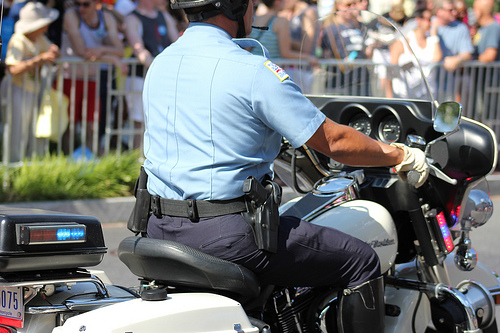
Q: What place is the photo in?
A: It is at the street.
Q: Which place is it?
A: It is a street.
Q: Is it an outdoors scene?
A: Yes, it is outdoors.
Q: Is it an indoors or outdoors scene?
A: It is outdoors.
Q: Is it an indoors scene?
A: No, it is outdoors.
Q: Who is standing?
A: The people are standing.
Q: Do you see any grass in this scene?
A: Yes, there is grass.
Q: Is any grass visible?
A: Yes, there is grass.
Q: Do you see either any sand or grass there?
A: Yes, there is grass.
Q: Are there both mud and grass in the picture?
A: No, there is grass but no mud.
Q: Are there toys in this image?
A: No, there are no toys.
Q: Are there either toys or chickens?
A: No, there are no toys or chickens.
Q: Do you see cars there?
A: No, there are no cars.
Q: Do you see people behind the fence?
A: Yes, there is a person behind the fence.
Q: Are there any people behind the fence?
A: Yes, there is a person behind the fence.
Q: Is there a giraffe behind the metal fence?
A: No, there is a person behind the fence.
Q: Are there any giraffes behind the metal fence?
A: No, there is a person behind the fence.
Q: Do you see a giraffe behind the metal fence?
A: No, there is a person behind the fence.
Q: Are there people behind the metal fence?
A: Yes, there is a person behind the fence.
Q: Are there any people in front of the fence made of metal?
A: No, the person is behind the fence.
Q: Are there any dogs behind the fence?
A: No, there is a person behind the fence.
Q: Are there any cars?
A: No, there are no cars.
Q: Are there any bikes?
A: Yes, there is a bike.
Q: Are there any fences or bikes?
A: Yes, there is a bike.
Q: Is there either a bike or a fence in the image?
A: Yes, there is a bike.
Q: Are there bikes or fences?
A: Yes, there is a bike.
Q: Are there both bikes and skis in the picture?
A: No, there is a bike but no skis.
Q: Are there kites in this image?
A: No, there are no kites.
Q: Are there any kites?
A: No, there are no kites.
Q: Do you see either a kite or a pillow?
A: No, there are no kites or pillows.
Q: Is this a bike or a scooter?
A: This is a bike.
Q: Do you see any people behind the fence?
A: Yes, there is a person behind the fence.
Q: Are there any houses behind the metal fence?
A: No, there is a person behind the fence.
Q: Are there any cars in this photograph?
A: No, there are no cars.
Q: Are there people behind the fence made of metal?
A: Yes, there is a person behind the fence.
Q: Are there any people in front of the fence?
A: No, the person is behind the fence.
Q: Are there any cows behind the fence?
A: No, there is a person behind the fence.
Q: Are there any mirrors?
A: Yes, there is a mirror.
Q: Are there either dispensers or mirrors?
A: Yes, there is a mirror.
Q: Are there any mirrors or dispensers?
A: Yes, there is a mirror.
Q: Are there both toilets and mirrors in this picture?
A: No, there is a mirror but no toilets.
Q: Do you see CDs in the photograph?
A: No, there are no cds.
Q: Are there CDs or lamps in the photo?
A: No, there are no CDs or lamps.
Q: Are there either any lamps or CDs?
A: No, there are no CDs or lamps.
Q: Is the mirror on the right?
A: Yes, the mirror is on the right of the image.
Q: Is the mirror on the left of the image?
A: No, the mirror is on the right of the image.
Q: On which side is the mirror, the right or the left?
A: The mirror is on the right of the image.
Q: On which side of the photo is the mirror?
A: The mirror is on the right of the image.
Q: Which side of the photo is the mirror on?
A: The mirror is on the right of the image.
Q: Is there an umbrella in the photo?
A: No, there are no umbrellas.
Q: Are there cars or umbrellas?
A: No, there are no umbrellas or cars.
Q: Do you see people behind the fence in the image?
A: Yes, there are people behind the fence.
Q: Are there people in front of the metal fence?
A: No, the people are behind the fence.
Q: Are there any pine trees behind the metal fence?
A: No, there are people behind the fence.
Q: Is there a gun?
A: Yes, there is a gun.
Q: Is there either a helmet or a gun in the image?
A: Yes, there is a gun.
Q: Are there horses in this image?
A: No, there are no horses.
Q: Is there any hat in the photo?
A: Yes, there is a hat.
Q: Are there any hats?
A: Yes, there is a hat.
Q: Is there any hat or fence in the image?
A: Yes, there is a hat.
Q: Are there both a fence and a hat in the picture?
A: Yes, there are both a hat and a fence.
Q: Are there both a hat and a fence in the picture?
A: Yes, there are both a hat and a fence.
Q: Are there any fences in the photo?
A: Yes, there is a fence.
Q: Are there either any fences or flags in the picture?
A: Yes, there is a fence.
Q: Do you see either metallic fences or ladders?
A: Yes, there is a metal fence.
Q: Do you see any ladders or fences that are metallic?
A: Yes, the fence is metallic.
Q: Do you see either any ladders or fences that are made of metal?
A: Yes, the fence is made of metal.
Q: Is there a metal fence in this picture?
A: Yes, there is a metal fence.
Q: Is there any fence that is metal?
A: Yes, there is a metal fence.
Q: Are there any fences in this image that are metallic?
A: Yes, there is a fence that is metallic.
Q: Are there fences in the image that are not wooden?
A: Yes, there is a metallic fence.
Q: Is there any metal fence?
A: Yes, there is a fence that is made of metal.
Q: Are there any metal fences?
A: Yes, there is a fence that is made of metal.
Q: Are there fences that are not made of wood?
A: Yes, there is a fence that is made of metal.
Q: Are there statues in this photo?
A: No, there are no statues.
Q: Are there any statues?
A: No, there are no statues.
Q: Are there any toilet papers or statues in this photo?
A: No, there are no statues or toilet papers.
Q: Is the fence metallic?
A: Yes, the fence is metallic.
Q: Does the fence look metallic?
A: Yes, the fence is metallic.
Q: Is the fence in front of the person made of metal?
A: Yes, the fence is made of metal.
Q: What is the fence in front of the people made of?
A: The fence is made of metal.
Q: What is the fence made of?
A: The fence is made of metal.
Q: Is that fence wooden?
A: No, the fence is metallic.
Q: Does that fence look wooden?
A: No, the fence is metallic.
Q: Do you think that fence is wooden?
A: No, the fence is metallic.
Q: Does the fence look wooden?
A: No, the fence is metallic.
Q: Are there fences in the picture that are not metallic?
A: No, there is a fence but it is metallic.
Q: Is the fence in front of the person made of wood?
A: No, the fence is made of metal.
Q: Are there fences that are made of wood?
A: No, there is a fence but it is made of metal.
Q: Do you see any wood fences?
A: No, there is a fence but it is made of metal.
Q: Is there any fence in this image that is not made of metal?
A: No, there is a fence but it is made of metal.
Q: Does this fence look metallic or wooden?
A: The fence is metallic.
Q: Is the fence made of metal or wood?
A: The fence is made of metal.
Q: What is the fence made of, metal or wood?
A: The fence is made of metal.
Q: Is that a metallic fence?
A: Yes, that is a metallic fence.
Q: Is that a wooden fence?
A: No, that is a metallic fence.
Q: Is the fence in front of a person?
A: Yes, the fence is in front of a person.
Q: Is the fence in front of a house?
A: No, the fence is in front of a person.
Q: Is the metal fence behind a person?
A: No, the fence is in front of a person.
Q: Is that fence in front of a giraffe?
A: No, the fence is in front of a person.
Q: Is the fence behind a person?
A: No, the fence is in front of a person.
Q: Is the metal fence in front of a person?
A: Yes, the fence is in front of a person.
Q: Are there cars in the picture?
A: No, there are no cars.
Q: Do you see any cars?
A: No, there are no cars.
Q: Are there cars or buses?
A: No, there are no cars or buses.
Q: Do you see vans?
A: No, there are no vans.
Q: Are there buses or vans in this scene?
A: No, there are no vans or buses.